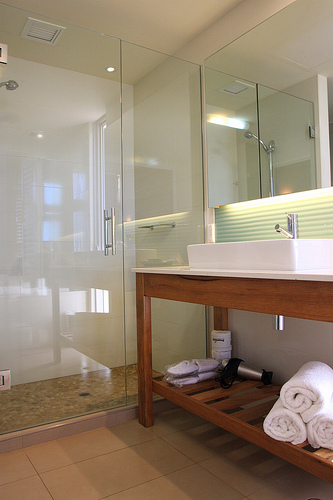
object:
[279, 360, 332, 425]
towels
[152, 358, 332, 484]
shelf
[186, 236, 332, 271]
sink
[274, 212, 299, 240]
faucet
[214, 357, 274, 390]
blow dryer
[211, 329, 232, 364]
toilet paper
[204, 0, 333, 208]
mirror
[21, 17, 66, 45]
vent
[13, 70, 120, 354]
shower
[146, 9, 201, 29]
ceiling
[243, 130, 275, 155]
shower head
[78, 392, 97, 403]
drain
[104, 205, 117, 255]
handle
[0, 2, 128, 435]
door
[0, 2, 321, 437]
bathroom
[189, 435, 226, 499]
ground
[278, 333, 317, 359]
wall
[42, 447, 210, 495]
floor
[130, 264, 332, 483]
table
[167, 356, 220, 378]
slippers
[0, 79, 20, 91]
tap